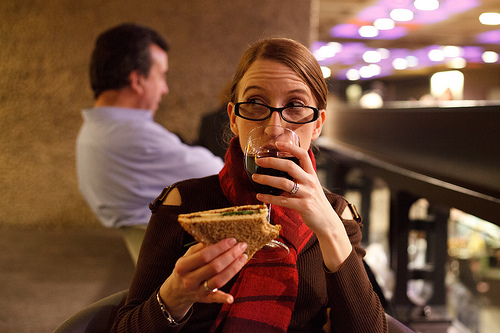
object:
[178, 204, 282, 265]
sandwich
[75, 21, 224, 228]
man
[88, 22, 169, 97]
hair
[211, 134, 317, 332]
scarf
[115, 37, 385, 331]
woman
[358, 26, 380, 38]
lights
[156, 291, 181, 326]
bracelet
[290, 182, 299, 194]
ring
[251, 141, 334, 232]
hand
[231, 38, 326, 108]
hair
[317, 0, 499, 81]
ceiling